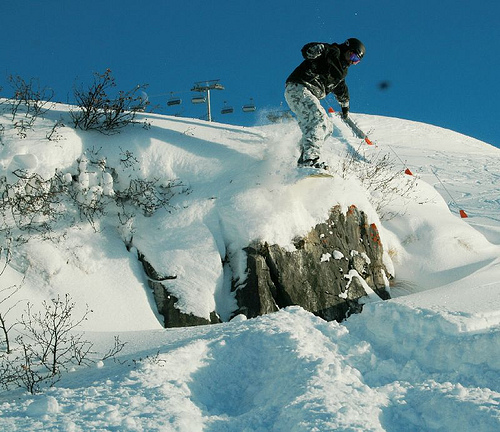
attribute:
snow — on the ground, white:
[7, 136, 500, 431]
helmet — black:
[340, 38, 364, 65]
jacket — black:
[283, 40, 357, 102]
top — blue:
[4, 3, 499, 133]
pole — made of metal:
[205, 81, 215, 123]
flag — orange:
[455, 207, 470, 219]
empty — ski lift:
[167, 93, 209, 109]